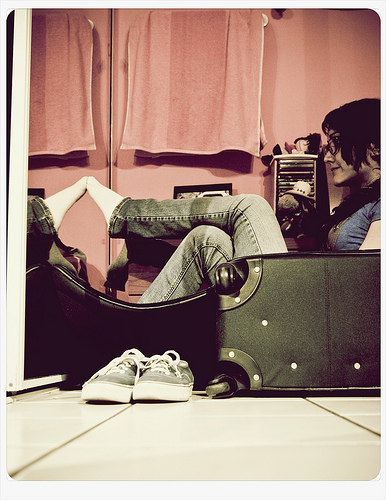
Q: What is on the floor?
A: Tennis shoes.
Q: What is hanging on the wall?
A: A towel.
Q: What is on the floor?
A: A rolling suitcase.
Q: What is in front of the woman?
A: A mirror.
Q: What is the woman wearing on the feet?
A: White socks.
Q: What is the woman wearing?
A: Jeans.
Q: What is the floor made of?
A: Ceramic tiles.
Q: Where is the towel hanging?
A: On the wall.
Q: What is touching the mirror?
A: The woman's foot.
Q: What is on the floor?
A: The side of a suitcase.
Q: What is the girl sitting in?
A: Suitcase.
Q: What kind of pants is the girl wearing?
A: Jeans.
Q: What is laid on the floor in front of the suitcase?
A: Shoes.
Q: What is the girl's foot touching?
A: Mirror.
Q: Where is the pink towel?
A: Hanging on wall.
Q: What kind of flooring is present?
A: Tile.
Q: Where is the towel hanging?
A: On wall.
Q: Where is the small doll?
A: Atop CD case.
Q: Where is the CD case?
A: Behind girl.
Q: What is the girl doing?
A: Sitting in a suitcase.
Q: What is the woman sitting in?
A: A suitcase.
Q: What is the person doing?
A: Sitting on the floor.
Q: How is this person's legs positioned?
A: Crossed.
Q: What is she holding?
A: Book.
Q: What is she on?
A: Seat.